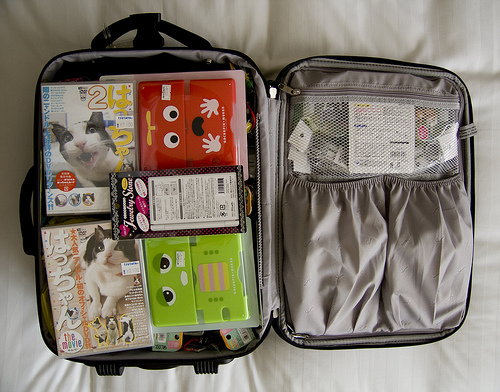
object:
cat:
[50, 111, 128, 188]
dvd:
[41, 76, 137, 217]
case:
[96, 70, 249, 181]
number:
[84, 84, 110, 112]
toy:
[216, 325, 256, 351]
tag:
[54, 168, 76, 192]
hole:
[225, 332, 233, 341]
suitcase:
[25, 10, 479, 375]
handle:
[18, 158, 39, 258]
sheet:
[0, 1, 499, 392]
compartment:
[284, 84, 463, 177]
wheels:
[94, 358, 134, 376]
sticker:
[120, 259, 144, 277]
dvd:
[40, 217, 157, 361]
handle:
[89, 8, 212, 57]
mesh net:
[284, 84, 464, 185]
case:
[138, 233, 262, 334]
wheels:
[190, 356, 220, 380]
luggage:
[19, 9, 482, 379]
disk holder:
[137, 230, 249, 328]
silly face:
[152, 243, 237, 309]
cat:
[80, 223, 141, 322]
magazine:
[32, 220, 155, 360]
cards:
[146, 171, 237, 226]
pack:
[140, 215, 267, 334]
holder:
[134, 81, 243, 180]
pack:
[97, 67, 252, 183]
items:
[345, 101, 421, 176]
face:
[92, 236, 138, 273]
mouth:
[74, 147, 101, 169]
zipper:
[285, 86, 462, 105]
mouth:
[100, 259, 116, 269]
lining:
[281, 69, 475, 338]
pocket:
[275, 175, 388, 342]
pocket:
[383, 173, 473, 333]